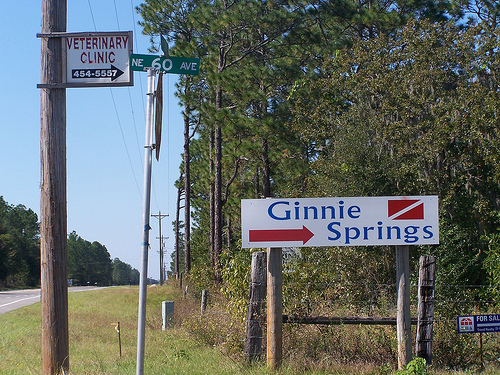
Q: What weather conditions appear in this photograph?
A: It is clear.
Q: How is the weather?
A: It is clear.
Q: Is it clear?
A: Yes, it is clear.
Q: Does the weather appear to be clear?
A: Yes, it is clear.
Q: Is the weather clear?
A: Yes, it is clear.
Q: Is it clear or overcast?
A: It is clear.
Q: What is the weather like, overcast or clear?
A: It is clear.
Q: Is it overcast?
A: No, it is clear.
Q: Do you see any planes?
A: No, there are no planes.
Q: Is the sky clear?
A: Yes, the sky is clear.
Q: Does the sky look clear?
A: Yes, the sky is clear.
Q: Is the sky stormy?
A: No, the sky is clear.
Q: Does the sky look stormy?
A: No, the sky is clear.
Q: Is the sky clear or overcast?
A: The sky is clear.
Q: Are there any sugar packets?
A: No, there are no sugar packets.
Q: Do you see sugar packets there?
A: No, there are no sugar packets.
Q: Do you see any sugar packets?
A: No, there are no sugar packets.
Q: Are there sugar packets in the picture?
A: No, there are no sugar packets.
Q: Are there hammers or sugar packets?
A: No, there are no sugar packets or hammers.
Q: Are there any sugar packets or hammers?
A: No, there are no sugar packets or hammers.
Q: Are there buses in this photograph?
A: No, there are no buses.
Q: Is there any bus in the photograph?
A: No, there are no buses.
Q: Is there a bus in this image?
A: No, there are no buses.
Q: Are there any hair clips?
A: No, there are no hair clips.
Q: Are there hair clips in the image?
A: No, there are no hair clips.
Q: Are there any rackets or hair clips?
A: No, there are no hair clips or rackets.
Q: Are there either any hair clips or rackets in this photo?
A: No, there are no hair clips or rackets.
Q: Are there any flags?
A: No, there are no flags.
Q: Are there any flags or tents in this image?
A: No, there are no flags or tents.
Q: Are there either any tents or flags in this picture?
A: No, there are no flags or tents.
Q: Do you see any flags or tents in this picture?
A: No, there are no flags or tents.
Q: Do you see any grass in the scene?
A: Yes, there is grass.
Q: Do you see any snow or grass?
A: Yes, there is grass.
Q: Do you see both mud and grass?
A: No, there is grass but no mud.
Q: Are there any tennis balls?
A: No, there are no tennis balls.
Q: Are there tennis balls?
A: No, there are no tennis balls.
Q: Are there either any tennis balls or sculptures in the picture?
A: No, there are no tennis balls or sculptures.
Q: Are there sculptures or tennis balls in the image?
A: No, there are no tennis balls or sculptures.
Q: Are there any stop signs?
A: Yes, there is a stop sign.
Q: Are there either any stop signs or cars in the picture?
A: Yes, there is a stop sign.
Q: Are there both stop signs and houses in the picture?
A: No, there is a stop sign but no houses.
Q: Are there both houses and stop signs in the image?
A: No, there is a stop sign but no houses.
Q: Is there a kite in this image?
A: No, there are no kites.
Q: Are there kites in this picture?
A: No, there are no kites.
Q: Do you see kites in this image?
A: No, there are no kites.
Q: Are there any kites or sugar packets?
A: No, there are no kites or sugar packets.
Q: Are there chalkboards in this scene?
A: No, there are no chalkboards.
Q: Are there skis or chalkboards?
A: No, there are no chalkboards or skis.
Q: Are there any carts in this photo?
A: No, there are no carts.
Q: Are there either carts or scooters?
A: No, there are no carts or scooters.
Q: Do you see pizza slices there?
A: No, there are no pizza slices.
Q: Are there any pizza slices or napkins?
A: No, there are no pizza slices or napkins.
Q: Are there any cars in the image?
A: No, there are no cars.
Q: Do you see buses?
A: No, there are no buses.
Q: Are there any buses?
A: No, there are no buses.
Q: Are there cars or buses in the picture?
A: No, there are no buses or cars.